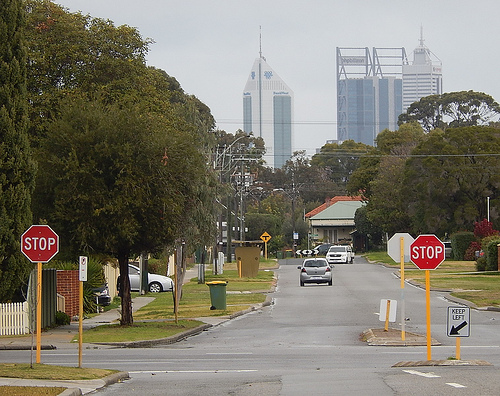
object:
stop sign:
[405, 233, 445, 273]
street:
[266, 254, 499, 395]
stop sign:
[15, 224, 57, 368]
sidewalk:
[12, 363, 109, 394]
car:
[295, 258, 334, 288]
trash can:
[206, 279, 228, 309]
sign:
[261, 236, 276, 267]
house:
[316, 196, 385, 250]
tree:
[40, 81, 207, 313]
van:
[324, 241, 352, 262]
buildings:
[401, 27, 445, 138]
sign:
[448, 307, 469, 337]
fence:
[1, 302, 35, 335]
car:
[112, 263, 172, 294]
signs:
[378, 236, 415, 333]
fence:
[42, 275, 86, 325]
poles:
[390, 251, 435, 357]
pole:
[422, 268, 431, 360]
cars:
[297, 241, 355, 285]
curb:
[139, 327, 185, 351]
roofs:
[337, 43, 406, 75]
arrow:
[446, 320, 465, 337]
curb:
[227, 300, 255, 320]